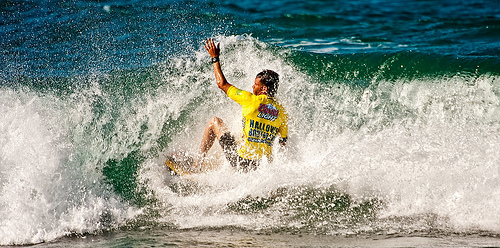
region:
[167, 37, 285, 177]
a man is wake boarding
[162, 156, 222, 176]
wake board is orange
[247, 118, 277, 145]
writing on the shirt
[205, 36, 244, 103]
arm is raised up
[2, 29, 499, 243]
the foam is white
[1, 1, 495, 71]
blue water in the background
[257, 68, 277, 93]
man has brown hair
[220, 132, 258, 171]
man is wearing shorts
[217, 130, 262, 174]
the shorts are black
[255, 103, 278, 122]
the shirt says Coors Light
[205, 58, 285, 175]
man is in water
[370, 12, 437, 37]
water is blue in color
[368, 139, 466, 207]
part of the water waves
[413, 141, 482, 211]
watr wavesa re white in color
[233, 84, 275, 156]
the t shirt is yellow in color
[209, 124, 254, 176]
the short is black in color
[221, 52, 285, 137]
man has raised his hand up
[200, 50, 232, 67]
the watch is black in color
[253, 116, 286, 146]
words are written in blue color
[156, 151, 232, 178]
the surfboard is orange in color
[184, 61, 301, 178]
THIS IS A PERSON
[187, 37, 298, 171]
THIS PERSON IS SURFING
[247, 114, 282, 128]
THIS IS A YELLOW T SHIRT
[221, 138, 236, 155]
THESE ARE BLACK SHORTS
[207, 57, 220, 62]
THIS IS A WATCH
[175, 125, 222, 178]
THIS IS A LEG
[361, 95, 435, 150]
THIS IS A WAVE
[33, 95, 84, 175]
THIS IS A WAVE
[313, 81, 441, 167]
THIS IS A WAVE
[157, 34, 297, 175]
person wearing a yellow shirt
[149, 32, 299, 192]
person riding on a surfboard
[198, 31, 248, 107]
arm of a person in the yellow shirt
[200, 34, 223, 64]
hand of a person in the yellow shirt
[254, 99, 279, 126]
logo on a bright yellow shirt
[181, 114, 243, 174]
leg of a person in the yellow shirt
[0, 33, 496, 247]
large wave in the ocean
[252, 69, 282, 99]
head of a person in the yellow shirt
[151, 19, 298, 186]
person riding a wave on a surfboard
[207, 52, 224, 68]
black watch on a wrist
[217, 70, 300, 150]
this is person is surfing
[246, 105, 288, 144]
this is a yellow shist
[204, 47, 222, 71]
this is a watch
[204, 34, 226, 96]
this is a hand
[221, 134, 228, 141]
this is a black short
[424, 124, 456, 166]
this is a wave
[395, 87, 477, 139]
this is a wave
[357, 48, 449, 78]
this is a wave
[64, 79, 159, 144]
this is a wave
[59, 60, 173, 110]
this is a wave